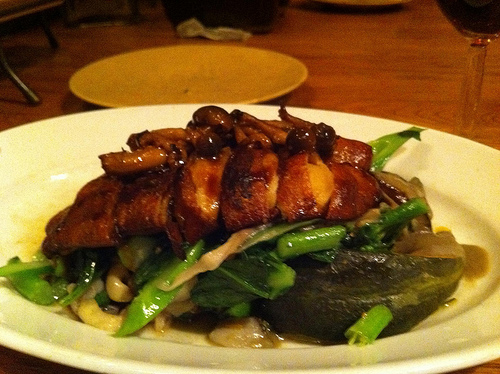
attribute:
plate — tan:
[56, 38, 309, 105]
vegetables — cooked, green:
[14, 195, 479, 336]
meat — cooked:
[39, 162, 396, 247]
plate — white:
[3, 99, 499, 369]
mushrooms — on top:
[107, 122, 323, 162]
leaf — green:
[8, 244, 75, 317]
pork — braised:
[49, 136, 418, 230]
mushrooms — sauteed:
[98, 96, 337, 162]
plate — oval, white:
[9, 113, 485, 363]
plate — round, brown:
[58, 61, 321, 118]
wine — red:
[437, 2, 486, 38]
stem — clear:
[465, 39, 488, 89]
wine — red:
[444, 4, 491, 57]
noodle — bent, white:
[100, 266, 163, 324]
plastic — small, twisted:
[158, 12, 290, 52]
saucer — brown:
[62, 37, 311, 104]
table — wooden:
[15, 6, 497, 144]